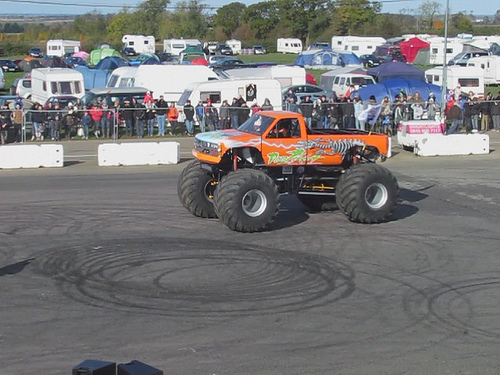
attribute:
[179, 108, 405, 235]
monster truck — orange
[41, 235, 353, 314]
track — by fence, circular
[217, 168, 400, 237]
tires — attached to truck, large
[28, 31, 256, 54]
campers — in a field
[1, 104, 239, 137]
spectators — behind fence, standing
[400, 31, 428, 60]
tent — large, red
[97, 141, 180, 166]
barricade — white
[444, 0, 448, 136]
pole — tall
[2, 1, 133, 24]
sky — blue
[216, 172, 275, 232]
tire — large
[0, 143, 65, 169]
block — white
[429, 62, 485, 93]
trailer — white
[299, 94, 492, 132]
crowd — standing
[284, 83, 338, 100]
car — silver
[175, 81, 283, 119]
van — white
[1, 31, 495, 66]
lot — full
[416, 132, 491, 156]
barrier — cement, behind truck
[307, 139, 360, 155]
skeleton — on truck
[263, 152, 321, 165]
writing — green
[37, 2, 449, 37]
trees — behind rvs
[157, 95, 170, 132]
person — standing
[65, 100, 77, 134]
person — standing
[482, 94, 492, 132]
person — standing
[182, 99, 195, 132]
he — standing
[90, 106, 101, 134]
she — standing